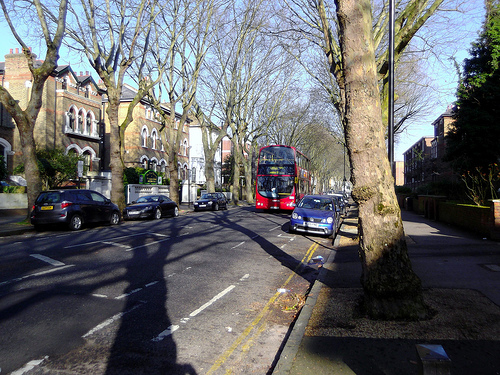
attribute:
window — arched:
[63, 105, 78, 133]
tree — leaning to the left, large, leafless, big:
[322, 3, 420, 316]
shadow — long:
[183, 204, 360, 296]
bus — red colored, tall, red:
[253, 148, 322, 213]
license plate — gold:
[40, 203, 57, 211]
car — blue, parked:
[285, 188, 344, 238]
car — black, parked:
[26, 187, 125, 228]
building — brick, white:
[4, 50, 190, 207]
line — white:
[147, 272, 250, 349]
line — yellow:
[208, 234, 324, 374]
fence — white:
[130, 184, 177, 200]